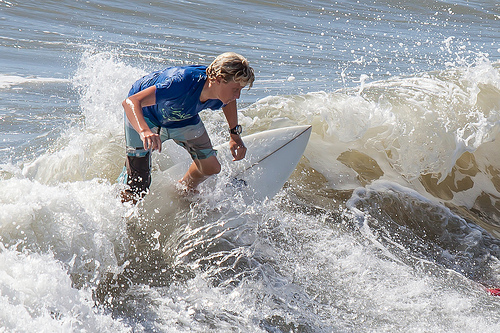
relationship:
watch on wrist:
[226, 120, 259, 141] [211, 121, 261, 152]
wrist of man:
[211, 121, 261, 152] [118, 51, 257, 207]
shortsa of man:
[121, 113, 217, 161] [118, 51, 257, 207]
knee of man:
[184, 157, 256, 201] [118, 51, 257, 207]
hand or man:
[223, 128, 262, 167] [118, 51, 257, 207]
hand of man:
[223, 128, 262, 167] [118, 51, 257, 207]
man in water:
[118, 34, 257, 228] [258, 7, 367, 86]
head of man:
[209, 39, 259, 105] [118, 34, 257, 228]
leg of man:
[114, 148, 160, 222] [118, 34, 257, 228]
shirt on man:
[121, 51, 214, 129] [118, 51, 257, 207]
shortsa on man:
[121, 113, 217, 161] [118, 51, 257, 207]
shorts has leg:
[121, 111, 211, 205] [114, 148, 160, 222]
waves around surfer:
[24, 73, 484, 302] [102, 42, 263, 207]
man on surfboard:
[118, 51, 257, 207] [119, 124, 314, 216]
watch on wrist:
[224, 120, 247, 138] [211, 121, 261, 152]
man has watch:
[118, 51, 257, 207] [226, 124, 242, 137]